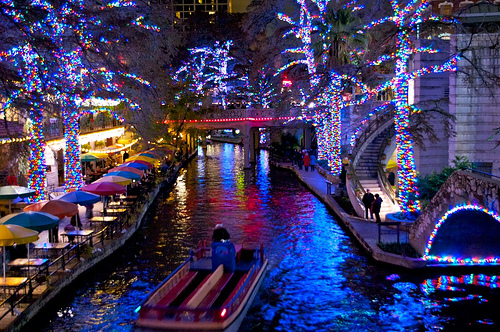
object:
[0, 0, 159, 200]
trees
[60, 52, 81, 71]
lights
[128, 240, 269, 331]
boat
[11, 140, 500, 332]
canal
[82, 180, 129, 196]
umbrellas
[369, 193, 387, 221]
people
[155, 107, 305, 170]
bridge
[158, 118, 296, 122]
light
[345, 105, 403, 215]
stairs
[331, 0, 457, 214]
tree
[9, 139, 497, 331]
water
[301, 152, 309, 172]
lady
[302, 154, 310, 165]
coat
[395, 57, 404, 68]
lights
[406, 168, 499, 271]
entrance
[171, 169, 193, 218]
reflection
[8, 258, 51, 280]
tables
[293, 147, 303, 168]
people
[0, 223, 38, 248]
umbrella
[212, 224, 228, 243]
person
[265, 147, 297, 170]
handrail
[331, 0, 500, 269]
building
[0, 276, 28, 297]
table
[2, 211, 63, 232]
umbrella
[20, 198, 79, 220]
umbrella